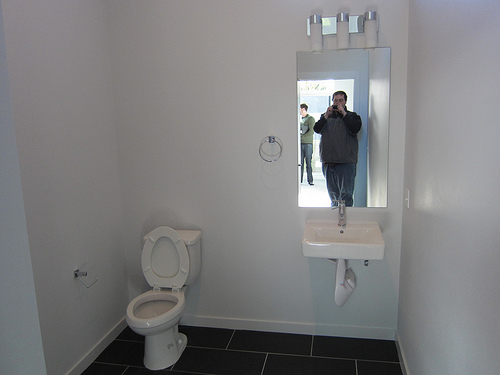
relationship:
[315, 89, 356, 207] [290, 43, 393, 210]
man picturing mirror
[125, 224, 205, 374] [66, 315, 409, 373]
toilet on tile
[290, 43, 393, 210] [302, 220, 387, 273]
mirror over sink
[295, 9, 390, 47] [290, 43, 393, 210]
lights above mirror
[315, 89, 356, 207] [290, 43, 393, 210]
man in mirror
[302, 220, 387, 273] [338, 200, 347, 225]
sink has faucet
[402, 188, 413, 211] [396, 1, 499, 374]
lightswitch on wall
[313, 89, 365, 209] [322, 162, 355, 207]
person wearing pants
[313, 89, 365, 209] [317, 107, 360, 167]
person wearing coat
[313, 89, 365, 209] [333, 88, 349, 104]
person has hair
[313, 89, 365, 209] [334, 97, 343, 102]
person has glasses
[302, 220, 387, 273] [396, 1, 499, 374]
sink attached to wall